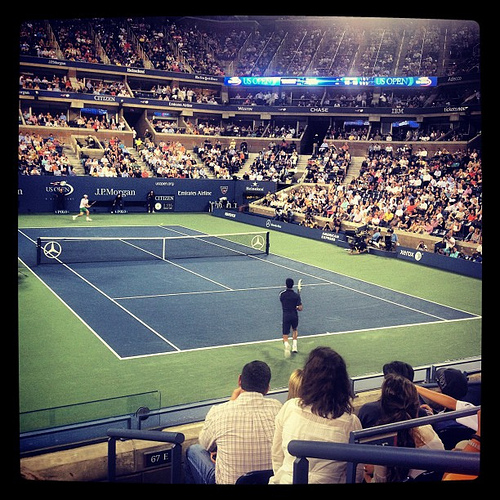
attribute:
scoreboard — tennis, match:
[222, 73, 437, 90]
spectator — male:
[217, 354, 287, 435]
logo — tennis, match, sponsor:
[216, 224, 276, 266]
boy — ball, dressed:
[144, 188, 159, 215]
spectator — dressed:
[194, 357, 283, 490]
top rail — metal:
[288, 438, 481, 475]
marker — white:
[33, 236, 70, 274]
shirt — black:
[279, 290, 303, 306]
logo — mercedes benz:
[250, 233, 265, 253]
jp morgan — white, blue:
[91, 186, 141, 199]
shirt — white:
[77, 196, 89, 210]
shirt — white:
[268, 396, 362, 484]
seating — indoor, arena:
[22, 22, 482, 266]